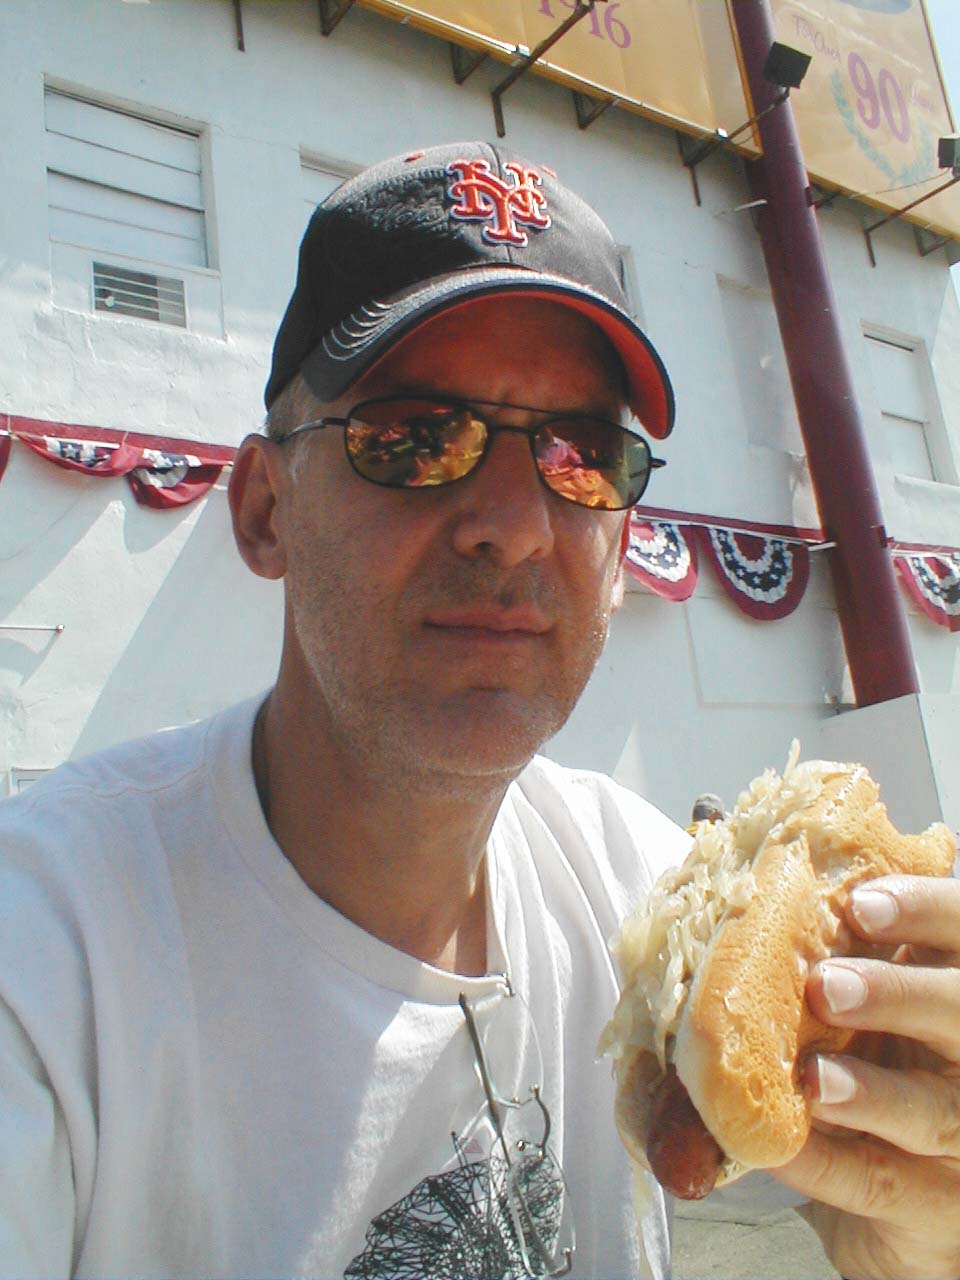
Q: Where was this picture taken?
A: Near man.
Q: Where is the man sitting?
A: At a ball game.